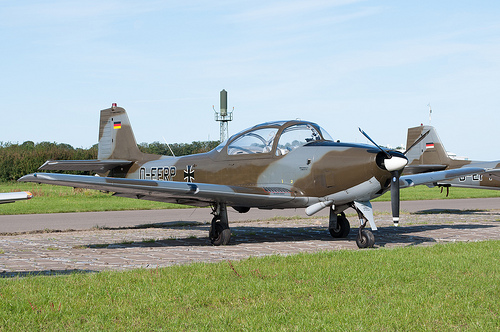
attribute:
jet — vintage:
[23, 98, 483, 234]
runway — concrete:
[27, 198, 478, 257]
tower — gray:
[214, 89, 231, 134]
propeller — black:
[388, 176, 403, 228]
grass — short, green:
[82, 257, 468, 331]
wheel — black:
[207, 217, 234, 245]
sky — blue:
[10, 6, 489, 77]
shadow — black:
[234, 222, 324, 242]